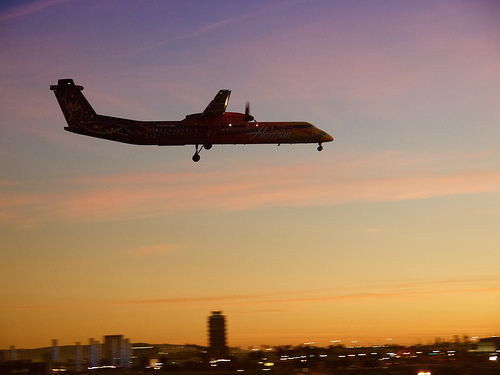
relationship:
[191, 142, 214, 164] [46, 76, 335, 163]
landing gear of airplane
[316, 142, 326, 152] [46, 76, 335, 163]
landing gear of airplane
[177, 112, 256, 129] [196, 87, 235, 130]
engine under wing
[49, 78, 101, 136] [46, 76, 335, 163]
tail of airplane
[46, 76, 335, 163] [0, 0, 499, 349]
airplane flying in sky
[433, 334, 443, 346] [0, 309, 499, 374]
tree on skyline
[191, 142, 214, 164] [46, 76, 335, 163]
landing gear on airplane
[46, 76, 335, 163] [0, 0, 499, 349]
airplane flying through sky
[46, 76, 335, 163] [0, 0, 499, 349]
airplane in sky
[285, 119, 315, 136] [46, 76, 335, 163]
cockpit of airplane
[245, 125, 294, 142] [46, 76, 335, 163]
word on airplane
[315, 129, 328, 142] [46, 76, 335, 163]
stripe on airplane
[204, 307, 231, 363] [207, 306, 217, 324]
building with pillar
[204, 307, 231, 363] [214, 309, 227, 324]
building with pillar